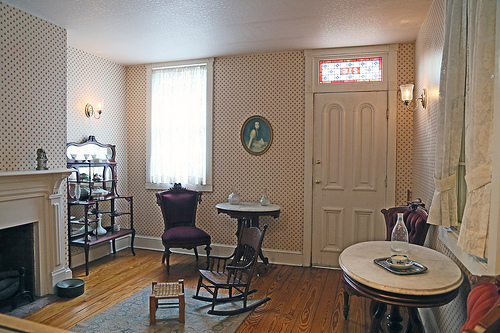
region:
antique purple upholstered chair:
[149, 182, 216, 272]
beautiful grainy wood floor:
[22, 238, 436, 330]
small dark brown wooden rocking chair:
[185, 219, 278, 318]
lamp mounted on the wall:
[390, 74, 437, 115]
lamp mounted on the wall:
[74, 92, 106, 123]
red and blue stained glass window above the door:
[308, 53, 390, 92]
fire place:
[0, 165, 76, 320]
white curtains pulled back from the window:
[428, 5, 498, 265]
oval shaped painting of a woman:
[234, 108, 279, 160]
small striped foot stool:
[136, 274, 193, 330]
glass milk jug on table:
[388, 208, 410, 253]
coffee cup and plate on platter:
[387, 252, 412, 268]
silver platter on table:
[372, 251, 427, 277]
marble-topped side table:
[337, 233, 464, 332]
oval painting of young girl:
[237, 111, 274, 157]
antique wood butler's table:
[65, 129, 141, 279]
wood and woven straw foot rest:
[147, 274, 187, 324]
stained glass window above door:
[315, 55, 387, 84]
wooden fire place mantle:
[0, 161, 71, 299]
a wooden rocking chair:
[188, 218, 274, 317]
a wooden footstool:
[140, 275, 192, 328]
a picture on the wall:
[232, 106, 279, 166]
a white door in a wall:
[296, 40, 398, 275]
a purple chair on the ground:
[147, 180, 220, 276]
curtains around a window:
[422, 4, 490, 279]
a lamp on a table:
[376, 201, 439, 283]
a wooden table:
[328, 234, 465, 326]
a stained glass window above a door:
[304, 48, 393, 91]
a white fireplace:
[0, 146, 82, 318]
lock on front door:
[311, 152, 325, 169]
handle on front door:
[308, 177, 323, 188]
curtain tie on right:
[463, 163, 490, 208]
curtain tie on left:
[433, 163, 458, 201]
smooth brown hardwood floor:
[296, 282, 317, 319]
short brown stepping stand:
[151, 279, 184, 297]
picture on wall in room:
[232, 107, 280, 161]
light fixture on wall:
[393, 74, 420, 116]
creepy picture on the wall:
[238, 111, 275, 156]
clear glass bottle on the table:
[384, 208, 418, 256]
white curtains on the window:
[437, 0, 495, 262]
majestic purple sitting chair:
[156, 182, 205, 264]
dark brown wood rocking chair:
[199, 221, 279, 304]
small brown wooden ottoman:
[141, 274, 190, 324]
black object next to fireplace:
[56, 273, 83, 301]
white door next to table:
[307, 85, 402, 273]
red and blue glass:
[314, 57, 384, 82]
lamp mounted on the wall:
[82, 90, 104, 120]